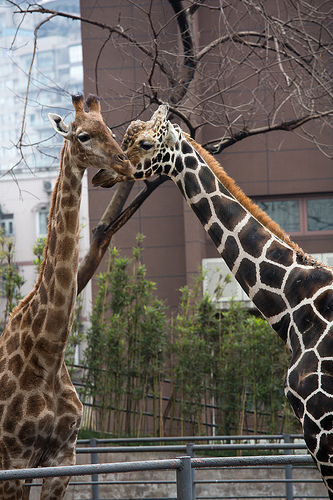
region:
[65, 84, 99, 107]
The horns on the giraffe's head on the left.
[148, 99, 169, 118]
The horns on the giraffe's head on the right.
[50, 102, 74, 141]
The giraffe's ear on the left.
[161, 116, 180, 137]
The giraffe's ear on the right.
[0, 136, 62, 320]
The mane on the giraffe's neck on the left.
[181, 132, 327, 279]
The mane on the giraffe's neck on the right.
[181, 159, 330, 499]
The black spots on the giraffe on the right.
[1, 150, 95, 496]
The brown spots on the giraffe on the left.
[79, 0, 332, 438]
The dark brown building in the background.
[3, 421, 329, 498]
The gray metal fence surrounding the giraffes.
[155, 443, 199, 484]
A metal fence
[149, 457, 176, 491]
A metal fence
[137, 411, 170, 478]
A metal fence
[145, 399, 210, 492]
A metal fence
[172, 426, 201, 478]
A metal fence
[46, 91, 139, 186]
a giraffe with horns.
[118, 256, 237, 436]
a green leafy tree.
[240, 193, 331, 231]
a window on the side of a building.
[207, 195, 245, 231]
a dark spot on a giraffe.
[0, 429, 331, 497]
a metal fence.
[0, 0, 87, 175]
a tall building with lots of windows.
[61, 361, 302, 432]
a green fence near trees.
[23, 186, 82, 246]
a window on a building.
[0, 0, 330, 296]
a tree with no leaves.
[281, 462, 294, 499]
a metal bar holding up a fence.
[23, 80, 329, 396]
two giraffes standing up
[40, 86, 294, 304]
two giraffes facing each other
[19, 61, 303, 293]
giraffes facing each other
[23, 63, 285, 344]
a tree behind a giraffe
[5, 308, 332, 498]
a fence in between giraffes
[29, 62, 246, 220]
giraffe's heads next to each other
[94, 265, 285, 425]
trees with green leaves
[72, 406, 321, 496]
a small metal fence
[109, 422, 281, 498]
a small metal baracade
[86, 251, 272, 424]
thing trees with leaves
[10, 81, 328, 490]
Two giraffes in an enclosure.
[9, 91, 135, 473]
A giraffe on the left side.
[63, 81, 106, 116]
Horns on giraffe on the left side.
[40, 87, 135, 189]
Head on giraffe on the left side.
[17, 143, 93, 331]
Neck on giraffe on the left side.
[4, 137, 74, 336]
Mane on giraffe on the left side.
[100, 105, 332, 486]
Giraffe on the right side.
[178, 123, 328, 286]
Mane on giraffe on right side.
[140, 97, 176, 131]
Horns on giraffe on the right side.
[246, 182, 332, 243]
Windows on building in background.